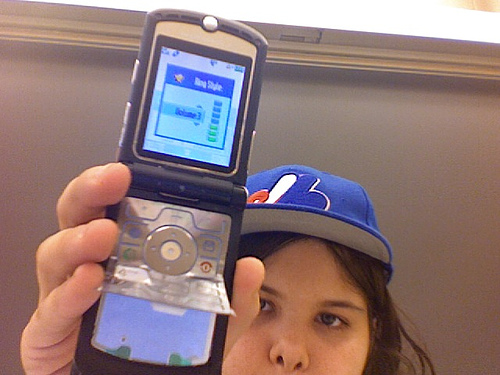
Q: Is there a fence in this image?
A: No, there are no fences.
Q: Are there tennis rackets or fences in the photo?
A: No, there are no fences or tennis rackets.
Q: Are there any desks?
A: No, there are no desks.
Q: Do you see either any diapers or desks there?
A: No, there are no desks or diapers.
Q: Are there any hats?
A: Yes, there is a hat.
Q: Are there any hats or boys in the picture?
A: Yes, there is a hat.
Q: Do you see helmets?
A: No, there are no helmets.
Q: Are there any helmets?
A: No, there are no helmets.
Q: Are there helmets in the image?
A: No, there are no helmets.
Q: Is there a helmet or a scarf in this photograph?
A: No, there are no helmets or scarves.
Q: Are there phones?
A: Yes, there is a phone.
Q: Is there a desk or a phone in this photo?
A: Yes, there is a phone.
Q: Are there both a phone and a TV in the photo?
A: No, there is a phone but no televisions.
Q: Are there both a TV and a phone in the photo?
A: No, there is a phone but no televisions.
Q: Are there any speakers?
A: No, there are no speakers.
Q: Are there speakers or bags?
A: No, there are no speakers or bags.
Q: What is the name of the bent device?
A: The device is a phone.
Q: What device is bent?
A: The device is a phone.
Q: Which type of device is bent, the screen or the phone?
A: The phone is bent.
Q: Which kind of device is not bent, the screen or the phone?
A: The screen is not bent.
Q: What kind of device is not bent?
A: The device is a screen.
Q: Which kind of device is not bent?
A: The device is a screen.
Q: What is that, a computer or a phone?
A: That is a phone.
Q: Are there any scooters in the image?
A: No, there are no scooters.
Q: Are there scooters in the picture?
A: No, there are no scooters.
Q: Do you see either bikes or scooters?
A: No, there are no scooters or bikes.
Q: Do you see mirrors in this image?
A: No, there are no mirrors.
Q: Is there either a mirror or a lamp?
A: No, there are no mirrors or lamps.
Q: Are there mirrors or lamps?
A: No, there are no mirrors or lamps.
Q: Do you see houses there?
A: No, there are no houses.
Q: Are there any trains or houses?
A: No, there are no houses or trains.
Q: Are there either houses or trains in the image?
A: No, there are no houses or trains.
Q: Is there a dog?
A: No, there are no dogs.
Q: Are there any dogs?
A: No, there are no dogs.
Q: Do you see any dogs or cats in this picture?
A: No, there are no dogs or cats.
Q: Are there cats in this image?
A: No, there are no cats.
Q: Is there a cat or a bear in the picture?
A: No, there are no cats or bears.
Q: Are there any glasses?
A: No, there are no glasses.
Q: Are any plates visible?
A: No, there are no plates.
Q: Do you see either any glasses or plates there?
A: No, there are no plates or glasses.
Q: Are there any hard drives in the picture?
A: No, there are no hard drives.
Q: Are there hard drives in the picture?
A: No, there are no hard drives.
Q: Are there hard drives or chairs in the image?
A: No, there are no hard drives or chairs.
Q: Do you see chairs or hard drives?
A: No, there are no hard drives or chairs.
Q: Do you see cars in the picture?
A: No, there are no cars.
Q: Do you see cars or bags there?
A: No, there are no cars or bags.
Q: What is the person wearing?
A: The person is wearing a hat.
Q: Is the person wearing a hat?
A: Yes, the person is wearing a hat.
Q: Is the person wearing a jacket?
A: No, the person is wearing a hat.